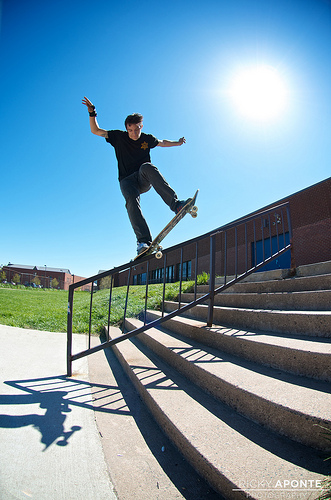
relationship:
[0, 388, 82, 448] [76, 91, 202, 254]
shadow of skateboarder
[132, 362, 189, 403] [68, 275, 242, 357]
shadow of guard railing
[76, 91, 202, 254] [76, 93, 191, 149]
skateboarder using arms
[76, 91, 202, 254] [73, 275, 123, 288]
skateboarder grinding on handrail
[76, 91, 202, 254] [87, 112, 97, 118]
skateboarder wearing wrist watch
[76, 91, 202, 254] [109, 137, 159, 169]
skateboarder wearing black shirt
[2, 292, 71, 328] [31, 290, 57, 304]
field of grass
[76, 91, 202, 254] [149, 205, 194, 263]
man on skateboard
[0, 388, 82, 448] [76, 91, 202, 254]
shadow of a man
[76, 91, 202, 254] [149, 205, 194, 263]
skateboarder on skateboard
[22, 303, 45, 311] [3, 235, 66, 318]
green tree in distance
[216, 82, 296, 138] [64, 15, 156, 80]
sun in sky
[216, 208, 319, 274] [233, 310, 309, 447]
building near stairs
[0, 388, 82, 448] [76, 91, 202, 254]
shadow on skateboarder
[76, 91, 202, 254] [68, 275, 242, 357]
skateboarder on railing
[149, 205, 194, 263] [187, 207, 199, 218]
skateboard with tires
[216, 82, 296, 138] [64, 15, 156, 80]
sun shining in sky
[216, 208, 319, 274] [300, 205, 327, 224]
building made of brick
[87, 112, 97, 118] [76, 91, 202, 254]
watch on skateboarder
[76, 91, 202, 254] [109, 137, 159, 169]
skateboarder wearing a shirt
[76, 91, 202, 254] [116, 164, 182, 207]
skateboarder wearing jeans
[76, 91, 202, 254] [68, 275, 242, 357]
skateboarder riding a railing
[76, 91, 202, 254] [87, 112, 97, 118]
skateboarder wearing a wrist watch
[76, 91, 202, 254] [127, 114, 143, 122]
skateboarder has brown hair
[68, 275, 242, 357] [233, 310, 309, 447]
railing on stairs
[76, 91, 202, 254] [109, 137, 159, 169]
skateboarder wears short sleeved shirt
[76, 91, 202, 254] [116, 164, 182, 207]
skateboarder wears jeans